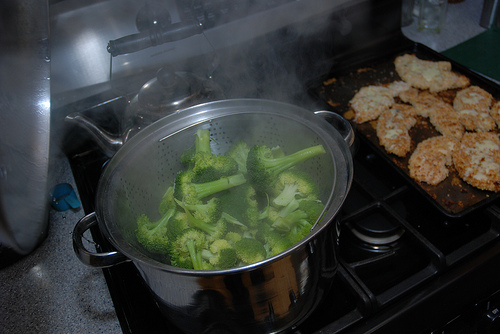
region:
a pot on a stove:
[53, 66, 375, 329]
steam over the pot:
[85, 35, 354, 278]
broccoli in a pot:
[123, 120, 321, 261]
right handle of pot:
[308, 97, 361, 152]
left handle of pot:
[63, 204, 132, 275]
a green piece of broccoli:
[234, 129, 329, 201]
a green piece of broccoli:
[168, 168, 242, 205]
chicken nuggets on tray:
[323, 33, 497, 234]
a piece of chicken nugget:
[408, 124, 458, 188]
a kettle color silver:
[55, 45, 230, 145]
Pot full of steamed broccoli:
[48, 73, 413, 314]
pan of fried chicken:
[312, 28, 487, 217]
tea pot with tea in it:
[71, 60, 236, 135]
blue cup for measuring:
[43, 175, 81, 217]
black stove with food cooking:
[49, 26, 494, 311]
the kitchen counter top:
[3, 39, 119, 325]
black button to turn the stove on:
[131, 8, 174, 40]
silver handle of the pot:
[49, 201, 120, 272]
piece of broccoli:
[244, 136, 321, 186]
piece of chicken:
[406, 134, 458, 182]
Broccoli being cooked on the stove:
[128, 125, 329, 272]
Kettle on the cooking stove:
[62, 16, 231, 161]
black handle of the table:
[107, 14, 207, 58]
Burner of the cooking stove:
[347, 180, 414, 246]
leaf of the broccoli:
[246, 143, 276, 195]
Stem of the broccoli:
[268, 142, 328, 177]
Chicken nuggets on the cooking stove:
[345, 52, 499, 213]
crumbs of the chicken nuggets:
[430, 177, 472, 211]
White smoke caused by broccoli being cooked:
[84, 0, 327, 232]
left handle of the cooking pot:
[69, 209, 131, 269]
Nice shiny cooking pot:
[71, 90, 359, 332]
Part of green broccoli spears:
[188, 180, 250, 227]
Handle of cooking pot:
[68, 210, 122, 272]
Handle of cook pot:
[312, 103, 363, 148]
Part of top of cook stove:
[341, 261, 416, 303]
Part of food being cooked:
[350, 80, 397, 112]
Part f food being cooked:
[405, 137, 453, 174]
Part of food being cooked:
[393, 53, 473, 97]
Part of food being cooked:
[456, 137, 495, 186]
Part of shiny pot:
[176, 288, 244, 322]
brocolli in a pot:
[129, 122, 324, 267]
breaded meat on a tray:
[349, 83, 388, 119]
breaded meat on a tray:
[412, 132, 459, 185]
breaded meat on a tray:
[377, 102, 415, 157]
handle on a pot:
[72, 211, 131, 266]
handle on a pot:
[312, 107, 353, 147]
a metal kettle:
[62, 24, 232, 153]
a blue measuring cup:
[48, 182, 81, 213]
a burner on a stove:
[350, 181, 410, 251]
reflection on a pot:
[130, 235, 341, 332]